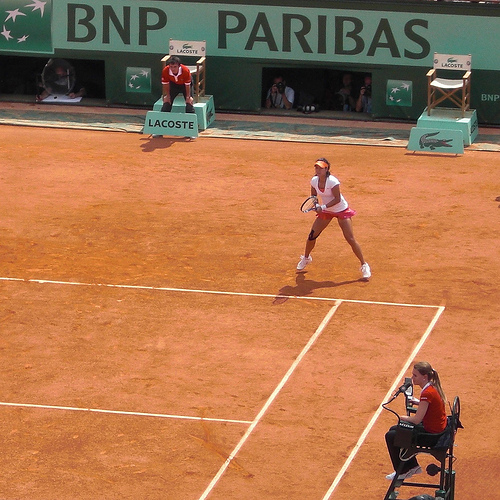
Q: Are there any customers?
A: No, there are no customers.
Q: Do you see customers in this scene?
A: No, there are no customers.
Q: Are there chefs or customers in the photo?
A: No, there are no customers or chefs.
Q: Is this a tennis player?
A: Yes, this is a tennis player.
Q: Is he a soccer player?
A: No, this is a tennis player.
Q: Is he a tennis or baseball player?
A: This is a tennis player.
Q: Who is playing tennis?
A: The player is playing tennis.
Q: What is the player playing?
A: The player is playing tennis.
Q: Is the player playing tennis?
A: Yes, the player is playing tennis.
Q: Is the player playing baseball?
A: No, the player is playing tennis.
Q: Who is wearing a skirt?
A: The player is wearing a skirt.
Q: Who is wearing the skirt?
A: The player is wearing a skirt.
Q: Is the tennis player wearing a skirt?
A: Yes, the player is wearing a skirt.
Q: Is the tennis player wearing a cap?
A: No, the player is wearing a skirt.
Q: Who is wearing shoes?
A: The player is wearing shoes.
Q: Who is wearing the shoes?
A: The player is wearing shoes.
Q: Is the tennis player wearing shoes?
A: Yes, the player is wearing shoes.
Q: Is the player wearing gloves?
A: No, the player is wearing shoes.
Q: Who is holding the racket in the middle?
A: The player is holding the racket.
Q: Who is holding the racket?
A: The player is holding the racket.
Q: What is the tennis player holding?
A: The player is holding the tennis racket.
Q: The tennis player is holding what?
A: The player is holding the tennis racket.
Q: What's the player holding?
A: The player is holding the tennis racket.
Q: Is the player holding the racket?
A: Yes, the player is holding the racket.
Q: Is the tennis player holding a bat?
A: No, the player is holding the racket.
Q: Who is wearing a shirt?
A: The player is wearing a shirt.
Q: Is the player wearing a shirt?
A: Yes, the player is wearing a shirt.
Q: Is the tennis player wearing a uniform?
A: No, the player is wearing a shirt.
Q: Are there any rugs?
A: No, there are no rugs.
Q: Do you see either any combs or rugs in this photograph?
A: No, there are no rugs or combs.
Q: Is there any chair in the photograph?
A: Yes, there is a chair.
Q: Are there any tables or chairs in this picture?
A: Yes, there is a chair.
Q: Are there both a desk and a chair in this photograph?
A: No, there is a chair but no desks.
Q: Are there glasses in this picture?
A: No, there are no glasses.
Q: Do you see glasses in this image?
A: No, there are no glasses.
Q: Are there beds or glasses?
A: No, there are no glasses or beds.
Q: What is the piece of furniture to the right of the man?
A: The piece of furniture is a chair.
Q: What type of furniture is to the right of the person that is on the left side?
A: The piece of furniture is a chair.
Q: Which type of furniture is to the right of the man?
A: The piece of furniture is a chair.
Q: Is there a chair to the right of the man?
A: Yes, there is a chair to the right of the man.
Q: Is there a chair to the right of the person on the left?
A: Yes, there is a chair to the right of the man.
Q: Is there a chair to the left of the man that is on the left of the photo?
A: No, the chair is to the right of the man.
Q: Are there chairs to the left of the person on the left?
A: No, the chair is to the right of the man.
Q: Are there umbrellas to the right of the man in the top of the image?
A: No, there is a chair to the right of the man.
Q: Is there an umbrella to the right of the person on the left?
A: No, there is a chair to the right of the man.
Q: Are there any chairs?
A: Yes, there is a chair.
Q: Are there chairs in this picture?
A: Yes, there is a chair.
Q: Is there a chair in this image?
A: Yes, there is a chair.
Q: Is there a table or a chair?
A: Yes, there is a chair.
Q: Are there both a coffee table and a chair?
A: No, there is a chair but no coffee tables.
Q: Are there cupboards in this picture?
A: No, there are no cupboards.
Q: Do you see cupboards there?
A: No, there are no cupboards.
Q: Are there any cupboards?
A: No, there are no cupboards.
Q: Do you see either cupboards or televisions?
A: No, there are no cupboards or televisions.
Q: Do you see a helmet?
A: No, there are no helmets.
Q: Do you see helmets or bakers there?
A: No, there are no helmets or bakers.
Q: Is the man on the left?
A: Yes, the man is on the left of the image.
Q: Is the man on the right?
A: No, the man is on the left of the image.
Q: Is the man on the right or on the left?
A: The man is on the left of the image.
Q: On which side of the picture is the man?
A: The man is on the left of the image.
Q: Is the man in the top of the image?
A: Yes, the man is in the top of the image.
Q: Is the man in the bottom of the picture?
A: No, the man is in the top of the image.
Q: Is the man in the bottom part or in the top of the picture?
A: The man is in the top of the image.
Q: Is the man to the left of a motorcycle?
A: No, the man is to the left of the chair.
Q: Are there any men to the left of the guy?
A: Yes, there is a man to the left of the guy.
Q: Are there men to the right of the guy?
A: No, the man is to the left of the guy.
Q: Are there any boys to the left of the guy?
A: No, there is a man to the left of the guy.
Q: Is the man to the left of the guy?
A: Yes, the man is to the left of the guy.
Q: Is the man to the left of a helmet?
A: No, the man is to the left of the guy.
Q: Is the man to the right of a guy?
A: No, the man is to the left of a guy.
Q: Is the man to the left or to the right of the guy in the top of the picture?
A: The man is to the left of the guy.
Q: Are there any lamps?
A: No, there are no lamps.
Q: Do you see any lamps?
A: No, there are no lamps.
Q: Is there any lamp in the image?
A: No, there are no lamps.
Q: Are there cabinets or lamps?
A: No, there are no lamps or cabinets.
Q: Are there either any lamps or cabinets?
A: No, there are no lamps or cabinets.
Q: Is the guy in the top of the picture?
A: Yes, the guy is in the top of the image.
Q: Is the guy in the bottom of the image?
A: No, the guy is in the top of the image.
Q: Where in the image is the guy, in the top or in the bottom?
A: The guy is in the top of the image.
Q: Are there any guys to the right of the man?
A: Yes, there is a guy to the right of the man.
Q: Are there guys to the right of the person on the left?
A: Yes, there is a guy to the right of the man.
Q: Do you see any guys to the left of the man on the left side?
A: No, the guy is to the right of the man.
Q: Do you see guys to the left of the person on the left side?
A: No, the guy is to the right of the man.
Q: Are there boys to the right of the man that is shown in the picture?
A: No, there is a guy to the right of the man.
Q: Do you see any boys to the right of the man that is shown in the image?
A: No, there is a guy to the right of the man.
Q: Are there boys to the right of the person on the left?
A: No, there is a guy to the right of the man.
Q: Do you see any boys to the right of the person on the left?
A: No, there is a guy to the right of the man.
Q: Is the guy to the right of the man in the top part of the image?
A: Yes, the guy is to the right of the man.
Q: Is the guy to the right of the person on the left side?
A: Yes, the guy is to the right of the man.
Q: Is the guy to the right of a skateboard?
A: No, the guy is to the right of the man.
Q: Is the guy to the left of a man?
A: No, the guy is to the right of a man.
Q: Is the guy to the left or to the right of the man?
A: The guy is to the right of the man.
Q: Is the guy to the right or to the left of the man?
A: The guy is to the right of the man.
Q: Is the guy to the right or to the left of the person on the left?
A: The guy is to the right of the man.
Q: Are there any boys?
A: No, there are no boys.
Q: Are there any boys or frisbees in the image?
A: No, there are no boys or frisbees.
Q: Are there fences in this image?
A: No, there are no fences.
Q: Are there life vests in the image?
A: No, there are no life vests.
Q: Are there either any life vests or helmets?
A: No, there are no life vests or helmets.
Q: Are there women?
A: Yes, there is a woman.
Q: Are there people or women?
A: Yes, there is a woman.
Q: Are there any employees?
A: No, there are no employees.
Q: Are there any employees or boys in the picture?
A: No, there are no employees or boys.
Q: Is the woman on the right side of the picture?
A: Yes, the woman is on the right of the image.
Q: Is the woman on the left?
A: No, the woman is on the right of the image.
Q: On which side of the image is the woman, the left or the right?
A: The woman is on the right of the image.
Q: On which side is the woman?
A: The woman is on the right of the image.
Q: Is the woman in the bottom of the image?
A: Yes, the woman is in the bottom of the image.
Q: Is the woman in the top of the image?
A: No, the woman is in the bottom of the image.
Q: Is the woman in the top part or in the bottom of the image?
A: The woman is in the bottom of the image.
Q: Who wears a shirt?
A: The woman wears a shirt.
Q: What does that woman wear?
A: The woman wears a shirt.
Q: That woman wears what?
A: The woman wears a shirt.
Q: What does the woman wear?
A: The woman wears a shirt.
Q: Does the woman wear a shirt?
A: Yes, the woman wears a shirt.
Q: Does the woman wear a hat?
A: No, the woman wears a shirt.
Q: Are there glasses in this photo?
A: No, there are no glasses.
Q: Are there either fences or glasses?
A: No, there are no glasses or fences.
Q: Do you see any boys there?
A: No, there are no boys.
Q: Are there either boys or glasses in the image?
A: No, there are no boys or glasses.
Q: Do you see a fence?
A: No, there are no fences.